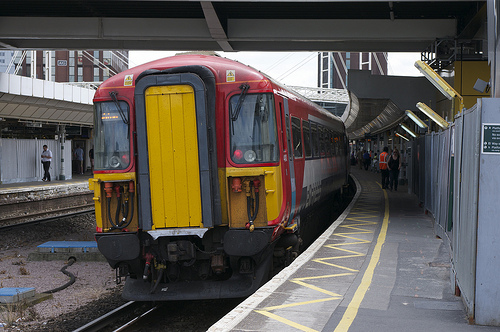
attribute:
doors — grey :
[273, 106, 299, 207]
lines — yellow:
[242, 217, 392, 330]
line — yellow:
[332, 226, 376, 291]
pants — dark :
[21, 157, 73, 201]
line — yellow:
[294, 186, 402, 305]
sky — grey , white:
[265, 58, 305, 83]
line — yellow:
[346, 211, 380, 222]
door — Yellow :
[140, 87, 208, 232]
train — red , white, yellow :
[85, 48, 355, 308]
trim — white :
[288, 149, 363, 184]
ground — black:
[0, 206, 124, 329]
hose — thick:
[40, 255, 79, 294]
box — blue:
[35, 239, 99, 253]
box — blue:
[1, 284, 39, 308]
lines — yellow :
[258, 159, 390, 329]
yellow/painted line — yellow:
[286, 262, 393, 312]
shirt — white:
[40, 147, 53, 164]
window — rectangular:
[226, 87, 279, 164]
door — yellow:
[142, 87, 202, 227]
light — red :
[238, 141, 259, 161]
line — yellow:
[362, 198, 402, 300]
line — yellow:
[219, 192, 391, 329]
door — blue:
[138, 77, 208, 227]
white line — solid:
[212, 197, 355, 329]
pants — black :
[39, 162, 54, 183]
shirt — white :
[41, 150, 52, 162]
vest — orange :
[376, 152, 391, 167]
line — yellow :
[262, 180, 393, 330]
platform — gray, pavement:
[211, 162, 467, 328]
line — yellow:
[259, 305, 318, 330]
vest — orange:
[376, 147, 391, 170]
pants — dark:
[375, 169, 389, 189]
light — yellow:
[412, 59, 462, 113]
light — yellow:
[412, 98, 444, 134]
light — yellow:
[400, 107, 424, 133]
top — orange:
[376, 149, 391, 175]